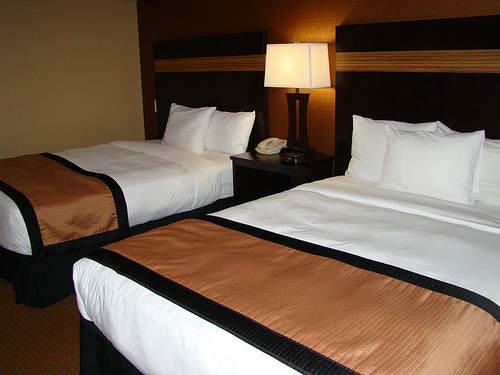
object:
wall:
[0, 2, 122, 128]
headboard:
[149, 29, 271, 139]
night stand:
[225, 138, 331, 198]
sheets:
[322, 206, 430, 236]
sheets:
[162, 160, 213, 198]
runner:
[103, 211, 495, 370]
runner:
[2, 147, 123, 240]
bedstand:
[224, 131, 334, 178]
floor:
[1, 321, 75, 371]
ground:
[353, 150, 377, 190]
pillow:
[353, 122, 434, 180]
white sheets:
[3, 137, 377, 259]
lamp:
[230, 22, 350, 175]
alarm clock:
[283, 151, 309, 164]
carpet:
[0, 313, 79, 372]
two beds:
[1, 66, 496, 374]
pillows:
[165, 100, 259, 155]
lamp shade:
[262, 26, 332, 90]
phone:
[252, 132, 288, 155]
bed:
[9, 107, 232, 274]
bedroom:
[1, 1, 497, 371]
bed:
[72, 15, 499, 372]